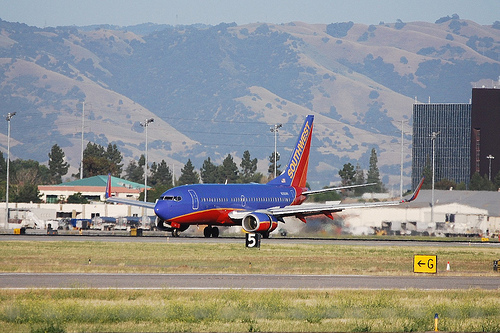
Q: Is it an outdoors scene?
A: Yes, it is outdoors.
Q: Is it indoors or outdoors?
A: It is outdoors.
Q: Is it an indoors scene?
A: No, it is outdoors.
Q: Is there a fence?
A: No, there are no fences.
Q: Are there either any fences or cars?
A: No, there are no fences or cars.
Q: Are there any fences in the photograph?
A: No, there are no fences.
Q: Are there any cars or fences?
A: No, there are no fences or cars.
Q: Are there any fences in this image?
A: No, there are no fences.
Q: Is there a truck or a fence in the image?
A: No, there are no fences or trucks.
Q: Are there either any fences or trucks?
A: No, there are no fences or trucks.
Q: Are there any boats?
A: No, there are no boats.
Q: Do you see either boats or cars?
A: No, there are no boats or cars.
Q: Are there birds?
A: No, there are no birds.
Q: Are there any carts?
A: No, there are no carts.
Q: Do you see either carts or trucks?
A: No, there are no carts or trucks.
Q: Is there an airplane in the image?
A: Yes, there is an airplane.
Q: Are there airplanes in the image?
A: Yes, there is an airplane.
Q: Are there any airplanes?
A: Yes, there is an airplane.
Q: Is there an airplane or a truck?
A: Yes, there is an airplane.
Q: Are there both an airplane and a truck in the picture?
A: No, there is an airplane but no trucks.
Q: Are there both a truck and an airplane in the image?
A: No, there is an airplane but no trucks.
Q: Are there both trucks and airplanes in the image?
A: No, there is an airplane but no trucks.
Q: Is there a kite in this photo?
A: No, there are no kites.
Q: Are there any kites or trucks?
A: No, there are no kites or trucks.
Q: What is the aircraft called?
A: The aircraft is an airplane.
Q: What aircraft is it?
A: The aircraft is an airplane.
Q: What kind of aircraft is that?
A: This is an airplane.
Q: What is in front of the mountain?
A: The plane is in front of the mountain.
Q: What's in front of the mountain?
A: The plane is in front of the mountain.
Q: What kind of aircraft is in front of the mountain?
A: The aircraft is an airplane.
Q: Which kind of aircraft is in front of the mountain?
A: The aircraft is an airplane.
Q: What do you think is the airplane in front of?
A: The airplane is in front of the mountain.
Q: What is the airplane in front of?
A: The airplane is in front of the mountain.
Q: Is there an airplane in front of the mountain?
A: Yes, there is an airplane in front of the mountain.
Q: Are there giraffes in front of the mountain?
A: No, there is an airplane in front of the mountain.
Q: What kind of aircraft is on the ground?
A: The aircraft is an airplane.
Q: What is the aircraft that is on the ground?
A: The aircraft is an airplane.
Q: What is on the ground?
A: The plane is on the ground.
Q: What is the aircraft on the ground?
A: The aircraft is an airplane.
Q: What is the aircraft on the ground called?
A: The aircraft is an airplane.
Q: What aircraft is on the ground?
A: The aircraft is an airplane.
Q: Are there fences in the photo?
A: No, there are no fences.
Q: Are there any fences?
A: No, there are no fences.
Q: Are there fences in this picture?
A: No, there are no fences.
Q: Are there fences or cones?
A: No, there are no fences or cones.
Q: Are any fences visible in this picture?
A: No, there are no fences.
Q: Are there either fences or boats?
A: No, there are no fences or boats.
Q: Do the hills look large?
A: Yes, the hills are large.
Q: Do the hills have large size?
A: Yes, the hills are large.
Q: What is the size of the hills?
A: The hills are large.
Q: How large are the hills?
A: The hills are large.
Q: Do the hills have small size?
A: No, the hills are large.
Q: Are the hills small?
A: No, the hills are large.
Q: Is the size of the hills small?
A: No, the hills are large.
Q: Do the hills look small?
A: No, the hills are large.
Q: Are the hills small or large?
A: The hills are large.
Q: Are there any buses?
A: No, there are no buses.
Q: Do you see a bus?
A: No, there are no buses.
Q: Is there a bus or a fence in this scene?
A: No, there are no buses or fences.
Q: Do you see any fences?
A: No, there are no fences.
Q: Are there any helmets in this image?
A: No, there are no helmets.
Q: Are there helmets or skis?
A: No, there are no helmets or skis.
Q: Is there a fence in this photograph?
A: No, there are no fences.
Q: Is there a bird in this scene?
A: No, there are no birds.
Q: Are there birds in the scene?
A: No, there are no birds.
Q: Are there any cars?
A: No, there are no cars.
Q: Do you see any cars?
A: No, there are no cars.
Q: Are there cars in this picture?
A: No, there are no cars.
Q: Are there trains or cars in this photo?
A: No, there are no cars or trains.